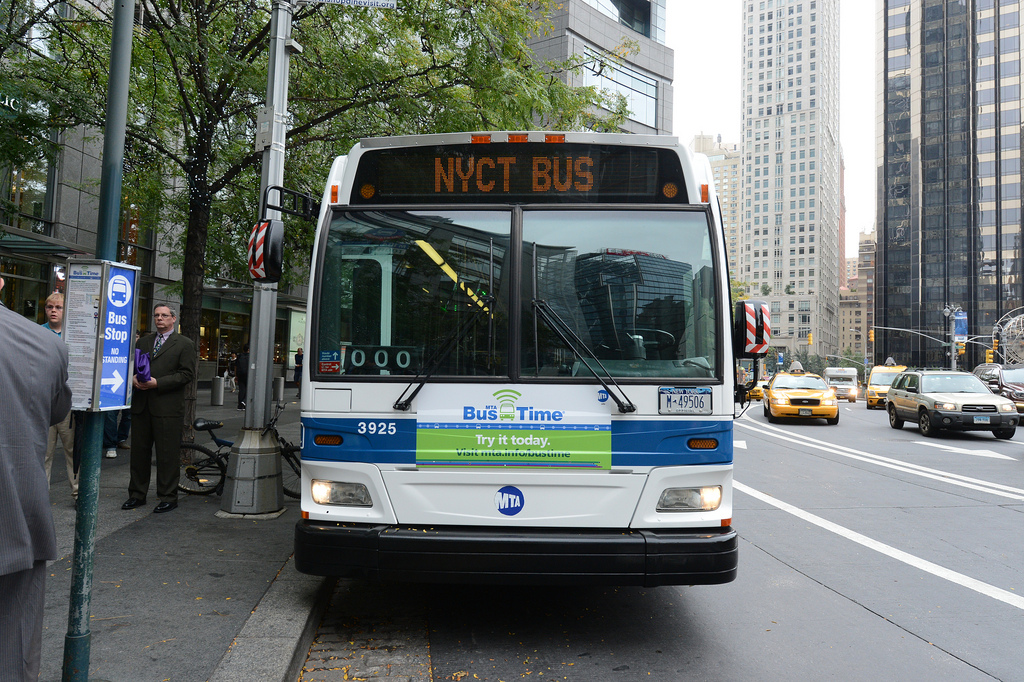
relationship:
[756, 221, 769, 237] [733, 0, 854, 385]
window on building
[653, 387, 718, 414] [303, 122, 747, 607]
plate on bus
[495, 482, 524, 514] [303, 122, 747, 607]
logo on bus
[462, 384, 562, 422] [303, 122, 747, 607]
logo on front of bus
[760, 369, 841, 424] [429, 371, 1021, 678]
taxi driving down road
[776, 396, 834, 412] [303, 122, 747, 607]
headlights on front of bus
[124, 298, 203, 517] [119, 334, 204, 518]
man in suit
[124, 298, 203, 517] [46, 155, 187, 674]
man standing at bus stop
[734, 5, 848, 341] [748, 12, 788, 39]
building with windows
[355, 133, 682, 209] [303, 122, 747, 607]
sign on front of bus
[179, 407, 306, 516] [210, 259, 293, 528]
bike propped on pole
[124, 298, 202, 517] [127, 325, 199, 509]
man wearing suit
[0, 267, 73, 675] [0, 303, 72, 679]
man wearing suit